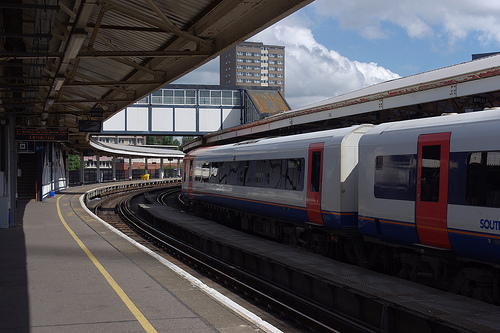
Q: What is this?
A: Train.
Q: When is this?
A: Daytime.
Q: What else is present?
A: Train tracks.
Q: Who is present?
A: Nobody.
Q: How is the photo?
A: Clear.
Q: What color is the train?
A: White.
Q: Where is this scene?
A: At a train station.